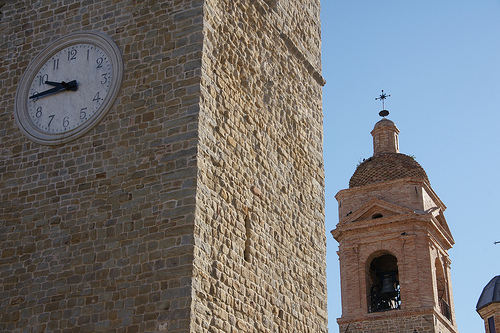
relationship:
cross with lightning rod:
[365, 81, 401, 119] [372, 92, 392, 103]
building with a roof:
[466, 265, 498, 327] [474, 280, 495, 305]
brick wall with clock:
[0, 2, 364, 330] [9, 21, 129, 160]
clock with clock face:
[8, 30, 125, 150] [13, 37, 131, 147]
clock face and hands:
[13, 37, 131, 147] [25, 73, 74, 103]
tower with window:
[327, 77, 468, 327] [354, 230, 423, 328]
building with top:
[331, 84, 458, 330] [338, 96, 445, 196]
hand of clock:
[32, 74, 78, 97] [6, 22, 137, 147]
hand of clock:
[26, 84, 79, 103] [6, 22, 137, 147]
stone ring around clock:
[59, 126, 77, 138] [24, 40, 116, 132]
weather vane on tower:
[375, 90, 389, 119] [332, 119, 457, 331]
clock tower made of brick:
[2, 1, 329, 328] [241, 186, 251, 196]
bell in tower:
[372, 260, 399, 301] [332, 119, 457, 331]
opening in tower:
[361, 250, 397, 311] [332, 119, 457, 331]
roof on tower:
[350, 153, 424, 182] [332, 119, 457, 331]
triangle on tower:
[352, 204, 399, 225] [341, 86, 462, 331]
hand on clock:
[30, 84, 79, 101] [24, 40, 116, 132]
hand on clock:
[46, 76, 78, 93] [19, 37, 120, 131]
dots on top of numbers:
[86, 46, 89, 49] [59, 44, 102, 65]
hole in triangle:
[372, 210, 382, 219] [342, 199, 412, 226]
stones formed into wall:
[410, 206, 426, 224] [342, 180, 440, 329]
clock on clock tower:
[8, 30, 125, 150] [2, 1, 329, 328]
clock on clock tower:
[4, 30, 124, 150] [2, 1, 329, 328]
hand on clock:
[46, 76, 78, 93] [17, 39, 111, 139]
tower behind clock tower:
[330, 86, 446, 331] [2, 1, 329, 328]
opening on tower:
[361, 250, 397, 311] [341, 86, 462, 331]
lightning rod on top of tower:
[372, 86, 399, 106] [332, 119, 457, 331]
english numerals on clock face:
[28, 46, 120, 133] [13, 37, 131, 147]